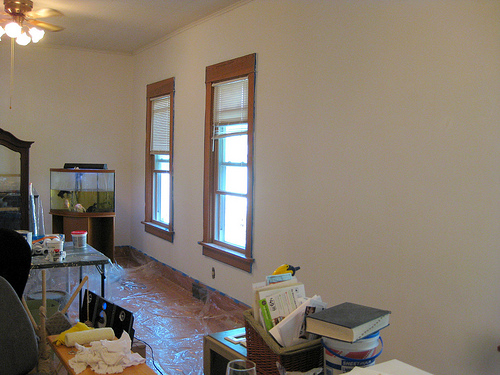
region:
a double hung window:
[206, 83, 246, 250]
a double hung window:
[151, 95, 171, 226]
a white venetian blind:
[211, 78, 247, 123]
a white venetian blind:
[148, 95, 168, 154]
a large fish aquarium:
[50, 165, 115, 213]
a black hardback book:
[305, 301, 392, 342]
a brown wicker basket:
[243, 308, 321, 373]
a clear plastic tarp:
[64, 245, 247, 373]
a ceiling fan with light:
[0, 0, 71, 45]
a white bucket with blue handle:
[319, 329, 384, 372]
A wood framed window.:
[196, 51, 258, 273]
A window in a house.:
[139, 75, 179, 242]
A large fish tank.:
[48, 163, 116, 213]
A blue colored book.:
[305, 299, 392, 341]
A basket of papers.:
[243, 272, 327, 374]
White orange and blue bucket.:
[321, 331, 386, 373]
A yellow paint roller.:
[63, 325, 113, 346]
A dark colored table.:
[30, 238, 109, 297]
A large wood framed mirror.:
[0, 123, 35, 233]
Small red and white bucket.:
[70, 228, 87, 249]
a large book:
[301, 299, 391, 345]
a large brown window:
[197, 53, 261, 270]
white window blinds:
[144, 90, 169, 155]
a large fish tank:
[50, 160, 116, 213]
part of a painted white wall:
[290, 76, 498, 210]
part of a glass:
[226, 355, 258, 373]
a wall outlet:
[208, 265, 215, 280]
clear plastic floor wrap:
[116, 246, 247, 373]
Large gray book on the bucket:
[303, 299, 392, 338]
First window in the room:
[198, 49, 259, 274]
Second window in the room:
[141, 71, 178, 245]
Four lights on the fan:
[3, 19, 38, 48]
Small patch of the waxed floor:
[139, 290, 171, 317]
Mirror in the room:
[4, 145, 28, 187]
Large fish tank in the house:
[46, 165, 120, 215]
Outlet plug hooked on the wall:
[207, 268, 217, 281]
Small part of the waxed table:
[79, 250, 93, 260]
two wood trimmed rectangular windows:
[123, 46, 260, 271]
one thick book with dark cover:
[303, 291, 394, 348]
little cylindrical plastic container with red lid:
[69, 228, 87, 249]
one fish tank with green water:
[45, 164, 119, 221]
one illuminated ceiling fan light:
[1, 5, 65, 50]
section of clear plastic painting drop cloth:
[101, 242, 231, 362]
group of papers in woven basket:
[248, 269, 322, 373]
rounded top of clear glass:
[227, 357, 257, 374]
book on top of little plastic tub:
[305, 294, 385, 373]